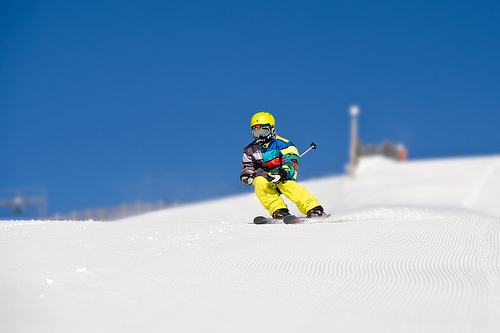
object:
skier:
[238, 111, 333, 225]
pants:
[252, 175, 320, 214]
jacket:
[240, 136, 301, 174]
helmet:
[249, 110, 277, 130]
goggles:
[250, 124, 275, 140]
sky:
[0, 0, 500, 221]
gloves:
[240, 167, 287, 185]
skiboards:
[253, 209, 332, 225]